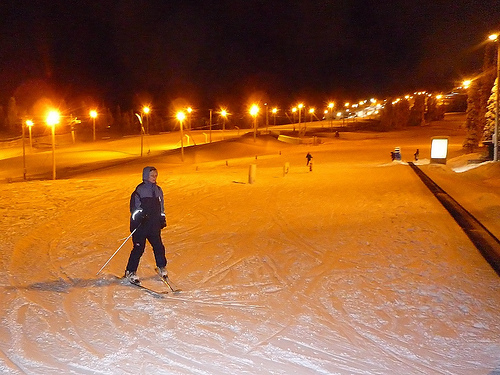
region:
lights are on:
[18, 71, 236, 115]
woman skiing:
[114, 169, 179, 323]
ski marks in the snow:
[241, 242, 343, 332]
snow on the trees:
[462, 79, 498, 137]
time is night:
[114, 6, 273, 64]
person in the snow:
[294, 133, 325, 176]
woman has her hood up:
[123, 162, 177, 203]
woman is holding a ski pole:
[94, 224, 140, 287]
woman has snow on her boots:
[125, 262, 193, 285]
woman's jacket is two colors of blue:
[135, 181, 180, 208]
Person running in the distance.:
[296, 150, 317, 170]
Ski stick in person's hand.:
[89, 218, 150, 283]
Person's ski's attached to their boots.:
[104, 257, 186, 304]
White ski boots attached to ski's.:
[119, 264, 176, 289]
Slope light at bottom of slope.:
[29, 105, 71, 186]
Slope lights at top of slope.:
[378, 88, 452, 105]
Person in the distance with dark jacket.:
[413, 141, 423, 164]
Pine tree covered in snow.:
[473, 75, 498, 152]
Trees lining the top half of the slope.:
[371, 88, 445, 136]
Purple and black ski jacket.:
[123, 159, 170, 244]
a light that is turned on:
[246, 99, 261, 141]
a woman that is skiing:
[98, 153, 178, 307]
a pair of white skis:
[111, 245, 189, 309]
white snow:
[211, 215, 473, 354]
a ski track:
[0, 101, 289, 185]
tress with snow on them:
[461, 63, 498, 147]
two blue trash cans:
[390, 142, 405, 164]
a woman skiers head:
[136, 163, 160, 192]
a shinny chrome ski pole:
[89, 215, 148, 280]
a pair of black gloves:
[132, 210, 174, 232]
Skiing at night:
[6, 3, 421, 309]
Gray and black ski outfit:
[124, 163, 178, 286]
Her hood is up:
[140, 162, 160, 187]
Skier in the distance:
[297, 145, 327, 175]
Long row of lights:
[3, 71, 382, 146]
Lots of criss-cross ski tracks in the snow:
[3, 228, 498, 373]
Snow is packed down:
[189, 187, 474, 367]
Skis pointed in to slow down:
[103, 255, 188, 302]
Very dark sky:
[46, 3, 436, 100]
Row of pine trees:
[376, 93, 451, 135]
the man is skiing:
[91, 150, 198, 291]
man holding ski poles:
[67, 208, 174, 313]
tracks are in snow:
[32, 222, 387, 369]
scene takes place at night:
[2, 0, 490, 359]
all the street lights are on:
[11, 78, 367, 155]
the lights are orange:
[2, 67, 374, 161]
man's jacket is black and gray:
[117, 180, 174, 227]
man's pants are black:
[117, 219, 169, 269]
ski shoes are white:
[118, 258, 187, 300]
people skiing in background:
[288, 133, 427, 189]